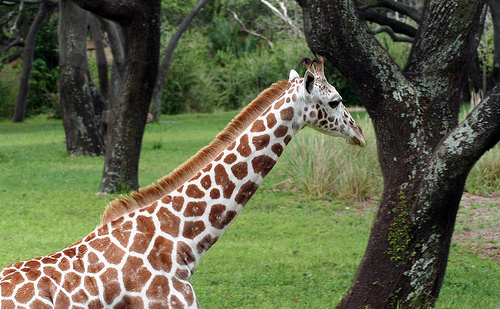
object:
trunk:
[334, 85, 499, 309]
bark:
[448, 125, 475, 163]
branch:
[435, 83, 500, 182]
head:
[285, 53, 365, 149]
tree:
[294, 0, 500, 308]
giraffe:
[0, 54, 366, 309]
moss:
[299, 0, 499, 308]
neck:
[94, 82, 304, 276]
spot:
[276, 105, 295, 122]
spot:
[180, 218, 207, 239]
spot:
[146, 233, 174, 274]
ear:
[301, 69, 316, 96]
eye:
[326, 97, 345, 109]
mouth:
[348, 133, 366, 150]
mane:
[96, 76, 289, 226]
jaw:
[343, 136, 356, 146]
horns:
[311, 55, 325, 76]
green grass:
[0, 102, 499, 309]